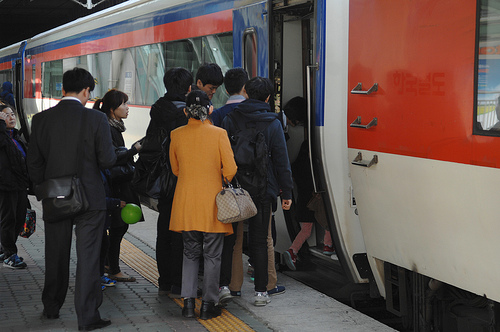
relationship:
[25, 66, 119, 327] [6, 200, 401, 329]
man standing on a grey platform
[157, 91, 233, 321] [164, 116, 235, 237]
woman with orange coat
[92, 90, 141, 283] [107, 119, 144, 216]
child with coat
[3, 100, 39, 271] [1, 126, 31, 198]
woman with coat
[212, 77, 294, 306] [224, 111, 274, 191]
man with black backpack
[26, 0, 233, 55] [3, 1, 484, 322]
stripe on train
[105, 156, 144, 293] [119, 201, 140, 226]
child with green ball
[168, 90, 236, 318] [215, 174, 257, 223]
woman with handbag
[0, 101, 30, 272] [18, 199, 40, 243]
woman with purse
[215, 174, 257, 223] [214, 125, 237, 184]
handbag on arm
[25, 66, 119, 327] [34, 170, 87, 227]
man with black bag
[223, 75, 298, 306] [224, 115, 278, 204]
man with black backpack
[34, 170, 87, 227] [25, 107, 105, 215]
bag on back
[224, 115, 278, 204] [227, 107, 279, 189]
backpack on back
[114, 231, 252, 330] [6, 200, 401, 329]
stripe on platform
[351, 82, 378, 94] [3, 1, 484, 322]
handle on side of train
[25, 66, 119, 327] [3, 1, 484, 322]
man waiting to board train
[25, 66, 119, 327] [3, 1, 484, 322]
man getting on a train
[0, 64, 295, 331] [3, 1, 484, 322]
group getting on a train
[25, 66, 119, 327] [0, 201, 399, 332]
man standing on a platform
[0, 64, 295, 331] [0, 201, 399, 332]
group standing on a platform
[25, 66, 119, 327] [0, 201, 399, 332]
man on platform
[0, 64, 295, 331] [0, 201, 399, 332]
group on platform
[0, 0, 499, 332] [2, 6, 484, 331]
train at station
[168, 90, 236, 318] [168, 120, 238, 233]
woman wearing a yellow coat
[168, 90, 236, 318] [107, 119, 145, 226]
woman wearing a coat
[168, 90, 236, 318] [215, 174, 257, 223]
woman holding handbag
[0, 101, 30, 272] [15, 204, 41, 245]
woman holding purse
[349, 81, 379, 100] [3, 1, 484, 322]
handle on train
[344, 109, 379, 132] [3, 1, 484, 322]
handle on train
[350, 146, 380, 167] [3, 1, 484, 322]
handle on train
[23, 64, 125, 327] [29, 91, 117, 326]
man wearing suit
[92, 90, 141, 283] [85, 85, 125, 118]
child has ponytail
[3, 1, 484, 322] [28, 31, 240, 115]
train has window